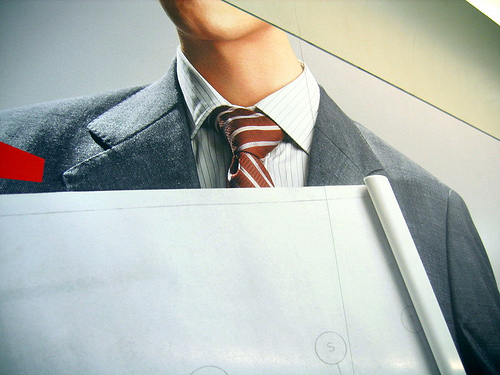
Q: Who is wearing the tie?
A: A man.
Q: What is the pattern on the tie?
A: Stripes.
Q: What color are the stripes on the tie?
A: Red and white.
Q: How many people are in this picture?
A: One.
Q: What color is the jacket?
A: Grey.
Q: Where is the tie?
A: Around the man's neck.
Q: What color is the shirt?
A: White.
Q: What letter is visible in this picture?
A: S.